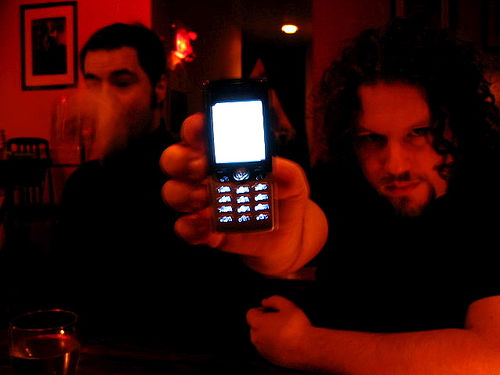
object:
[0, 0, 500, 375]
picture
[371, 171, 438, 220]
facial hair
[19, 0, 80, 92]
picture frame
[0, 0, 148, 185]
wall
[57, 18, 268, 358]
man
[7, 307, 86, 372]
glass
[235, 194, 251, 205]
buttons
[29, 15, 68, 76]
photograph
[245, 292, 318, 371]
hand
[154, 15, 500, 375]
man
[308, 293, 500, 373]
arm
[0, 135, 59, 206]
chair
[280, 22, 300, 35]
light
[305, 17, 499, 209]
black hair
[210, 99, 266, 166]
display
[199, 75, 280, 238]
illuminated smartphone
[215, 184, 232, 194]
buttons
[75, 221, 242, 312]
floor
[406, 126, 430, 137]
eyes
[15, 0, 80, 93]
frame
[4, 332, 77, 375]
liquid